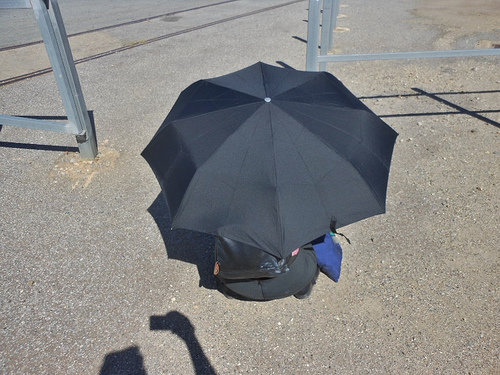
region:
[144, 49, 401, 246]
opened black umbrella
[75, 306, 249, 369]
shadow by black umbrella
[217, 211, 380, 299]
person sitting under umbrella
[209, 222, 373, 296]
person with blue bag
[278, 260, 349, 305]
person wearing black shoes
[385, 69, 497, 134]
shadow of metal bars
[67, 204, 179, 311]
concrete person is sitting on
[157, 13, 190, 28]
dark spot on concrete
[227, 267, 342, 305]
black pants of person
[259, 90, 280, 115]
white tip on black umbrella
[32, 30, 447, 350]
person crouched under umbrella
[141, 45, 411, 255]
open black umbrella above paved ground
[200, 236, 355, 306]
bags, buttocks and heels showing under umbrella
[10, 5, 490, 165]
silver frames erected near person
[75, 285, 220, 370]
shadow of person taking a photograph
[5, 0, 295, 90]
two metal rails embedded in ground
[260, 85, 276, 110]
white button centered in umbrella panels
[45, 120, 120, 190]
circle of tan adhesive used to erect frames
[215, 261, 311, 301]
dark seam on back of pants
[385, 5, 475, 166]
grey stones scattered across pavement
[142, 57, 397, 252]
a large black umbrella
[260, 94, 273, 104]
the metal tip on top of an umbrella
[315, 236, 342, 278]
a blue bag under an umbrella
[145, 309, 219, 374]
the shadow of a hand holding a camera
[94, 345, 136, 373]
the shadow of a person's head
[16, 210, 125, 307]
grey asphalt ground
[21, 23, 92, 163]
a grey metal gate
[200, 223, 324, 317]
the back end of a person crouching under an umbrella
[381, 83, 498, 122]
the shadow of a fence on the ground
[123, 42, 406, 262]
A black umbrella on a sunny day.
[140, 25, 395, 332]
Person under an umbrella.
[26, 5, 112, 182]
A gray pole next to a person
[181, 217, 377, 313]
Person under umbrella is crouching down.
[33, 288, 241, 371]
A shadow on the ground.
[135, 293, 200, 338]
Shadow of person holding a camera.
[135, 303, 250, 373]
Shadow of an arm.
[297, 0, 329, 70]
Another gray pole near the umbrella.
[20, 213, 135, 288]
Gravel on the ground.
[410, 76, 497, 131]
The shadow of a pole.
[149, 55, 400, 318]
a person under an umbrella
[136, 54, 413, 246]
a black umbrella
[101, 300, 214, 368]
the shadow of a person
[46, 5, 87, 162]
a metal support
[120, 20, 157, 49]
a set of rail tracks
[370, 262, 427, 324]
gray gravel on the ground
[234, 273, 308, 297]
black pants covering a bottom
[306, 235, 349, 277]
a blue bag sitting on the ground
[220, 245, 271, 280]
a black leather jacket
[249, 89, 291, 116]
a metal button on top of the umbrella